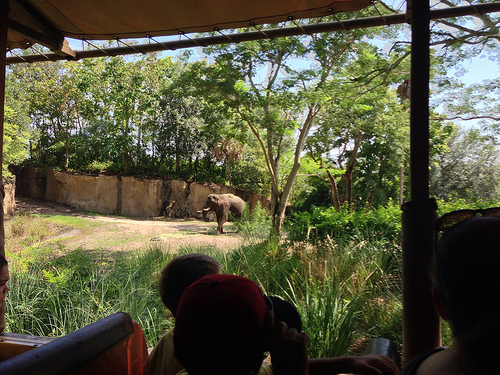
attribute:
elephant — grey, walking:
[198, 196, 249, 231]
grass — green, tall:
[12, 243, 401, 327]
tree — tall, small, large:
[177, 37, 414, 257]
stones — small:
[19, 166, 240, 217]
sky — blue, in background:
[429, 20, 500, 200]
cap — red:
[180, 275, 269, 338]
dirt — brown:
[15, 197, 249, 248]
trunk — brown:
[267, 184, 287, 244]